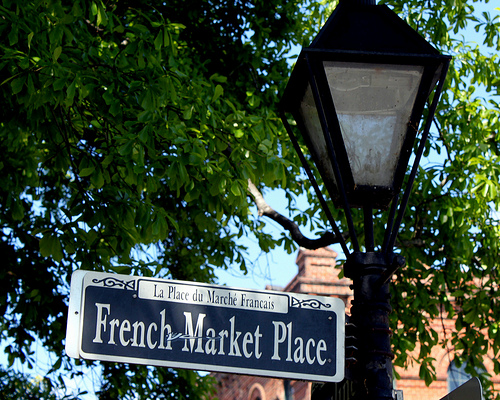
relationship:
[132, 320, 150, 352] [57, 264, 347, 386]
letter on a sign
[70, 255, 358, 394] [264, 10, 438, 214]
sign on light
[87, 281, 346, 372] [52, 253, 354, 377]
white letter on sign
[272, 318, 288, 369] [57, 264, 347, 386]
letter on sign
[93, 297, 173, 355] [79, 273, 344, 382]
french on sign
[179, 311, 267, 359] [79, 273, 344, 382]
market on sign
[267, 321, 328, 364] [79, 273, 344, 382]
place on sign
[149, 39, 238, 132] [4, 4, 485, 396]
leaves on tree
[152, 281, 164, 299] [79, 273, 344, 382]
la on sign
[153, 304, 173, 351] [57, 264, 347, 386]
letter on sign